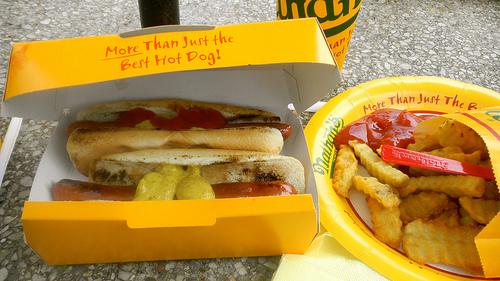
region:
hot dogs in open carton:
[6, 18, 338, 265]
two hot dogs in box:
[53, 95, 300, 202]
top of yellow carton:
[3, 17, 339, 95]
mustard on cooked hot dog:
[54, 170, 292, 197]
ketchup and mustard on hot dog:
[78, 105, 282, 131]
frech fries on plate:
[307, 76, 495, 279]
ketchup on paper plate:
[337, 107, 434, 150]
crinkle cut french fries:
[338, 125, 484, 260]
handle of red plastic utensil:
[381, 142, 490, 177]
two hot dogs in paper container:
[3, 10, 347, 252]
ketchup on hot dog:
[69, 107, 231, 135]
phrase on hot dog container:
[85, 27, 247, 72]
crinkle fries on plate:
[330, 95, 497, 271]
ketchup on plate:
[338, 105, 415, 147]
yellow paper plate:
[297, 73, 495, 280]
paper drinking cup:
[267, 0, 367, 79]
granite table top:
[2, 3, 497, 278]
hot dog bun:
[65, 102, 285, 172]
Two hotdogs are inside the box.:
[43, 92, 323, 254]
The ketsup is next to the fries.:
[329, 118, 384, 177]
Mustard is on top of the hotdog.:
[123, 162, 232, 212]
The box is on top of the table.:
[0, 108, 171, 278]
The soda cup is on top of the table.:
[270, 0, 372, 90]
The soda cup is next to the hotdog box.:
[222, 0, 368, 75]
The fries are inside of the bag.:
[412, 108, 499, 173]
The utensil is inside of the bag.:
[378, 132, 498, 183]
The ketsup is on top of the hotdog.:
[107, 98, 255, 145]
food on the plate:
[297, 81, 474, 246]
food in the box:
[10, 38, 297, 226]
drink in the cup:
[288, 3, 346, 58]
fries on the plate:
[374, 213, 465, 260]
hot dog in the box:
[8, 88, 289, 149]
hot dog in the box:
[79, 168, 274, 196]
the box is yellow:
[234, 225, 286, 245]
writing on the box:
[70, 20, 242, 64]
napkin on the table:
[276, 256, 311, 273]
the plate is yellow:
[332, 225, 371, 252]